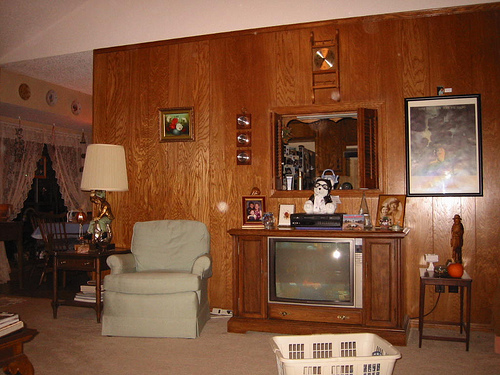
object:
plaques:
[235, 112, 252, 165]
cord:
[409, 286, 444, 321]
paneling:
[92, 0, 500, 331]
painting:
[157, 106, 196, 143]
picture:
[242, 194, 266, 230]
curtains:
[0, 115, 91, 232]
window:
[0, 116, 94, 239]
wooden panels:
[188, 49, 280, 98]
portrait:
[245, 199, 262, 223]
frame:
[241, 195, 266, 229]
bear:
[303, 178, 337, 215]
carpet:
[0, 296, 499, 375]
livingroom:
[0, 0, 500, 375]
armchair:
[98, 219, 213, 338]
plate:
[18, 82, 31, 100]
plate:
[46, 89, 58, 107]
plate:
[70, 99, 82, 116]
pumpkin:
[447, 263, 464, 278]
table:
[50, 249, 128, 324]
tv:
[268, 235, 365, 310]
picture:
[404, 84, 485, 198]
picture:
[156, 105, 196, 143]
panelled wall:
[91, 0, 500, 330]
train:
[100, 218, 214, 339]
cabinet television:
[225, 228, 411, 348]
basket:
[269, 331, 402, 374]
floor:
[0, 292, 500, 375]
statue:
[449, 214, 465, 264]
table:
[417, 267, 472, 352]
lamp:
[72, 143, 127, 255]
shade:
[80, 143, 129, 193]